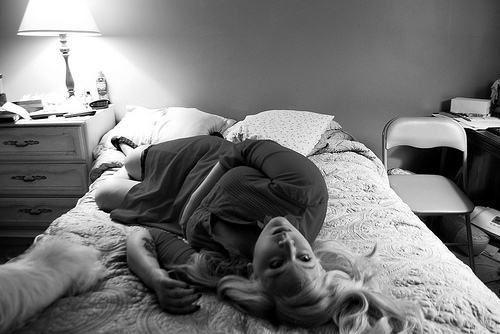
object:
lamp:
[14, 0, 102, 120]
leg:
[116, 135, 231, 181]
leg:
[91, 166, 183, 212]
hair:
[162, 236, 424, 334]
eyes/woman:
[266, 258, 286, 269]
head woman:
[244, 215, 327, 306]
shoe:
[110, 136, 138, 151]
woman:
[90, 136, 422, 334]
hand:
[146, 271, 205, 316]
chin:
[262, 214, 292, 230]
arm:
[124, 220, 202, 312]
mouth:
[268, 225, 295, 238]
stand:
[0, 103, 115, 238]